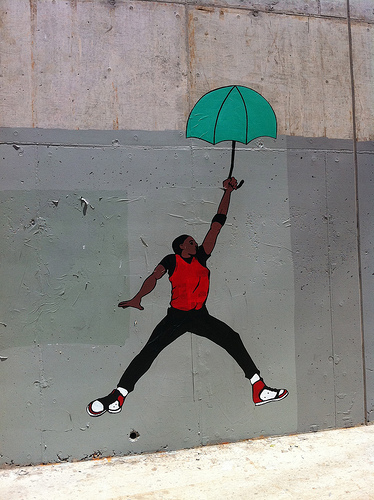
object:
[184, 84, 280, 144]
umbrella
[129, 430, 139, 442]
hole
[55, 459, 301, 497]
ground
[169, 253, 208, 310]
red shirt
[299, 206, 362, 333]
grey wall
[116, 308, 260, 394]
black pants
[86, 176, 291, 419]
man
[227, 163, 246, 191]
umbrella handle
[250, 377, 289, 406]
shoe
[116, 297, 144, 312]
hand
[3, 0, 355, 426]
wall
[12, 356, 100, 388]
section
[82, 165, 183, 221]
section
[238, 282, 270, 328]
section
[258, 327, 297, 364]
section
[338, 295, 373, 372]
section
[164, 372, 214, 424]
section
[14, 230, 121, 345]
section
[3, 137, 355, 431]
picture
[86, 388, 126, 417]
shoe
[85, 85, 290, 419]
drawing